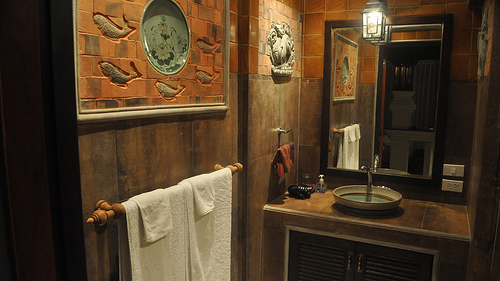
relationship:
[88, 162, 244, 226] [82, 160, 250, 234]
towel rack on towel rack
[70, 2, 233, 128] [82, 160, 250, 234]
picture above towel rack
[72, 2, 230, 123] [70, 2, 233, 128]
picture on picture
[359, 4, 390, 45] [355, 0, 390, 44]
light fixture with cover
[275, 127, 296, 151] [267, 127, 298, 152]
towel rack hanging on towel rack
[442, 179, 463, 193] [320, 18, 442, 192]
electrical outlets next to mirror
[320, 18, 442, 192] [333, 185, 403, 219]
mirror behind basin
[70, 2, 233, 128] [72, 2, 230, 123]
picture with picture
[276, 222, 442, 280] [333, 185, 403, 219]
cabinet under basin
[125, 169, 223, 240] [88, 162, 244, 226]
washcloths on top of towel rack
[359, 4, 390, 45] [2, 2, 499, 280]
light fixture in bathroom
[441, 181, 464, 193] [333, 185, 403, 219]
electrical outlets near basin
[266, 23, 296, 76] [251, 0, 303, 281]
sculpture on wall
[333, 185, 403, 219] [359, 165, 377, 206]
basin has a faucet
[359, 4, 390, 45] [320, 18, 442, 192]
light fixture over mirror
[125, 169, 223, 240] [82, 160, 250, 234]
washcloths on towel rack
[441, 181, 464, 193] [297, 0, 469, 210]
electrical outlets on wall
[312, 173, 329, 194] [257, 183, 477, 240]
soap on countertop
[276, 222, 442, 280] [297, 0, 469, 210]
cabinet in wall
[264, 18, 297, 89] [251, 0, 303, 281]
sculpture on wall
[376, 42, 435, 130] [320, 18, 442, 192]
window in mirror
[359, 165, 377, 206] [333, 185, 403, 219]
faucet in basin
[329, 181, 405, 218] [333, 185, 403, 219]
basin of basin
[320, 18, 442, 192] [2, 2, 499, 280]
mirror in bathroom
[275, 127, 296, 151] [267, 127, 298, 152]
towel rack on towel rack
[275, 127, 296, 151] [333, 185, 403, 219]
towel rack near basin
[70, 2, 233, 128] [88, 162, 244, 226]
picture over towel rack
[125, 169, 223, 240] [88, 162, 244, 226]
washcloths over towel rack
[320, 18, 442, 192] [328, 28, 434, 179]
mirror has reflection